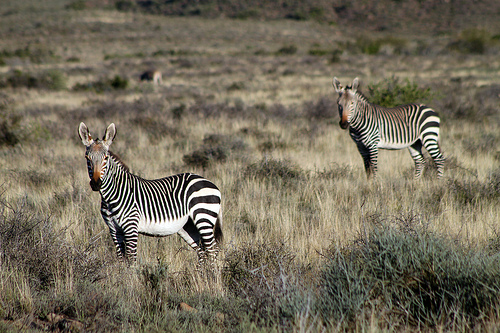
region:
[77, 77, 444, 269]
the zebras standing on the grass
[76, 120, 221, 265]
the zebra standing on the grass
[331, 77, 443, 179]
the zebra standing on the grass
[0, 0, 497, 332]
the tall brown grass in the area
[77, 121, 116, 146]
the ears on the zebra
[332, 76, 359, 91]
the ears on the zebra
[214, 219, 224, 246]
the black hair at the end of the tail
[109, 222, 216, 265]
the legs on the zebra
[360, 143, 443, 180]
the legs on the zebra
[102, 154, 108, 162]
the zebras left eye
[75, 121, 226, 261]
Black and white zebra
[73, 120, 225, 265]
Standing black and white zebra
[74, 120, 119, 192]
Brown on a zebra's face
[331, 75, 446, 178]
Zebra standing in a field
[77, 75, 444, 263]
Two zebras standing in a field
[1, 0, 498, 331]
Field of tall dry grass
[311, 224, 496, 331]
Green safari shrub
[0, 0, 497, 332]
Safari scenery with two zebras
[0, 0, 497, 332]
Sunny safari scenery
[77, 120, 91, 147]
Pointy ear of a zebra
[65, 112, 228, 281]
a xebra in the grass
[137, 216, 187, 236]
his stomach is white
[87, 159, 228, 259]
the stripes are black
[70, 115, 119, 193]
his face is brown and black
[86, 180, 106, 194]
his tip is black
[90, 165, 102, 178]
this part is brown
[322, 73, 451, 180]
this zebra has brown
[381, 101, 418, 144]
his stripes are black and brown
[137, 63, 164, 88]
this zebra is facing backwards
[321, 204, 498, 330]
a chunk of green grass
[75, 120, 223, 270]
Zebra standing in field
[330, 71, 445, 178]
Zebra standing in field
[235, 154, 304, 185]
Small green bush in field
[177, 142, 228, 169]
Small green bush in field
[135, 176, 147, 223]
Long black stripe on zebra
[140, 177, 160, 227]
Long black stripe on zebra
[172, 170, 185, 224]
Long black stripe on zebra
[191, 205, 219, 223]
Thick black stripe on zebra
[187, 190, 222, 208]
Thick black stripe on zebra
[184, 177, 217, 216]
Thick black stripe on zebra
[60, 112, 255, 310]
this is a zebra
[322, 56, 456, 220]
this is a zebra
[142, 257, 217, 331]
a shrub of trees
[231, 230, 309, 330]
a shrub of trees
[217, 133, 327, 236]
a shrub of trees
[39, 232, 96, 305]
a shrub of trees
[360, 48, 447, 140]
a shrub of trees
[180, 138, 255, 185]
a shrub of trees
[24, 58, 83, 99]
a shrub of trees